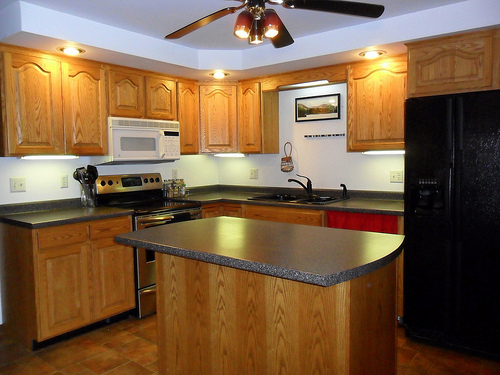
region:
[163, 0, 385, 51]
Ceiling fan with brown blades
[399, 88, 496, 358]
Black refrigerator with side by side doors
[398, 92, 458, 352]
Black refrigerator door with ice and drink dispenser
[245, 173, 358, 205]
Black double sink with black hardware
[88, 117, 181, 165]
White microwave oven with black digital display area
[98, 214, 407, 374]
Wood kitchen island with gray granite counter top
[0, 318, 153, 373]
Section of terracotta floor tiles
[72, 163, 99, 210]
Various kitchen utensils in a glass container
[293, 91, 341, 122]
Landscape print in black frame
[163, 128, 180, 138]
black panel on microwave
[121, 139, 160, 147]
grey glass on microwave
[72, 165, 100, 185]
spactulas in clear vase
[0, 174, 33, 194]
double light panel on wall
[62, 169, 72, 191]
single light panel on wall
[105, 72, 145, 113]
small door top left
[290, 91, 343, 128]
painting over top sink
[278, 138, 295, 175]
mitt hanging on wall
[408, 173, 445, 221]
ice maker on fridge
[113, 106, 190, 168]
white microwave in kitchen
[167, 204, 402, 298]
black and grey bar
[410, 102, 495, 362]
black fridge and freezer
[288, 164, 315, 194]
black faucet in sink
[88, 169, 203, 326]
black and silver range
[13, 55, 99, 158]
brown cabinets near microwave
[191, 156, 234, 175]
white backsplash behind range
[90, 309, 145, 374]
floor is brown tile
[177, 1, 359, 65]
black fan on ceiling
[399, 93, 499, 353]
Black two door refigerator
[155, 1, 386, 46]
Ceiling fan with lights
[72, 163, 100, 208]
Cooking utensils on counter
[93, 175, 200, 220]
Silver and black stove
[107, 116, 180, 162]
White microwave under cabinet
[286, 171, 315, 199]
Dark colored kitchen faucet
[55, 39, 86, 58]
round light in the ceiling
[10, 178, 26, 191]
Double white light switch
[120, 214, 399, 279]
Gray speckled counter top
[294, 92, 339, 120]
Picture hanging over sink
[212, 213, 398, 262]
the light reflected on the counter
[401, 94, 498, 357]
a black fridge to the right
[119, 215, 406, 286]
the kitchen counter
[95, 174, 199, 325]
an electrical stove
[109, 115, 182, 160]
a microwave above the stove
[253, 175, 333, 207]
this is a black sink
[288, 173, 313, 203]
the sink faucet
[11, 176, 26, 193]
a white light switch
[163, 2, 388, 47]
a turn off ceiling fan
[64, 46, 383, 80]
three lamps on